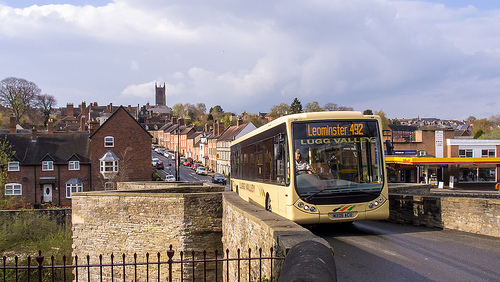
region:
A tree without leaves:
[1, 73, 41, 129]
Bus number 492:
[347, 120, 368, 137]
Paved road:
[325, 231, 498, 277]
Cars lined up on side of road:
[147, 134, 234, 191]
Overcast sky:
[5, 6, 495, 93]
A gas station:
[384, 147, 498, 203]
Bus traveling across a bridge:
[221, 114, 392, 229]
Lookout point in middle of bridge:
[67, 166, 247, 226]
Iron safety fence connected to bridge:
[4, 244, 284, 279]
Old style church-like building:
[144, 76, 179, 121]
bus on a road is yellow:
[213, 98, 400, 232]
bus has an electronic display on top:
[279, 110, 389, 145]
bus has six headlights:
[290, 192, 396, 212]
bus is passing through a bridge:
[159, 87, 496, 279]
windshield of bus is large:
[286, 116, 386, 207]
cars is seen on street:
[147, 140, 222, 180]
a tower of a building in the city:
[145, 70, 170, 105]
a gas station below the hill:
[387, 145, 497, 185]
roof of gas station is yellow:
[390, 146, 497, 164]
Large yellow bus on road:
[208, 108, 405, 245]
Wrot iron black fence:
[5, 241, 284, 281]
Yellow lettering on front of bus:
[301, 122, 373, 147]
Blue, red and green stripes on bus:
[326, 202, 368, 220]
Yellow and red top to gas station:
[392, 146, 499, 176]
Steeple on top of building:
[141, 78, 172, 113]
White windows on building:
[0, 145, 127, 200]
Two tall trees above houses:
[0, 71, 62, 131]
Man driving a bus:
[283, 151, 322, 193]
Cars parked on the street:
[155, 135, 229, 202]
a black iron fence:
[5, 238, 291, 280]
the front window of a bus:
[298, 143, 384, 191]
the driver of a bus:
[286, 149, 310, 178]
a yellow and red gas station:
[385, 147, 498, 187]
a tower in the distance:
[150, 81, 170, 106]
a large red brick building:
[0, 102, 166, 228]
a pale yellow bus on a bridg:
[221, 112, 394, 233]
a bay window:
[98, 151, 120, 179]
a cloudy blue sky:
[1, 1, 496, 118]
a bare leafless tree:
[0, 73, 47, 129]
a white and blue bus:
[227, 102, 401, 237]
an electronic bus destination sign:
[302, 116, 372, 138]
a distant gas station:
[386, 150, 498, 188]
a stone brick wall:
[66, 177, 313, 278]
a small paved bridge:
[203, 162, 498, 278]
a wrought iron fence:
[0, 239, 292, 278]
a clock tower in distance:
[150, 79, 165, 110]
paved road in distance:
[144, 143, 220, 193]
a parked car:
[193, 166, 205, 176]